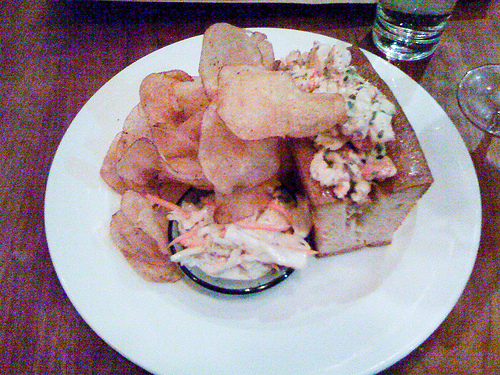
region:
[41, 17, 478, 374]
white plate on wood table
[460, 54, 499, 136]
base of wine glass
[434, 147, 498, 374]
shadow of plate on wood table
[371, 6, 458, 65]
clear glass cup on wood table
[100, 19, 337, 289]
crisps on white plate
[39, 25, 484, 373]
white plate with food on it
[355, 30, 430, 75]
shadow of glass on table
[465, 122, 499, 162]
shadow of wine glass on table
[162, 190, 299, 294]
small round dish on white plate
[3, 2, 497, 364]
wood table with plate and two glasses sitting on it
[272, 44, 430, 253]
lobster roll on a plate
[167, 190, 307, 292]
a small bowl of coleslaw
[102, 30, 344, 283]
kettle cooked potato chips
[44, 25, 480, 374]
a white plate with a sandwich and chips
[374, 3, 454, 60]
bottle of water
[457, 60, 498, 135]
bottom of a wine glass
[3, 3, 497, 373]
brown wooden table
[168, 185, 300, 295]
blue-rimmed tiny bowl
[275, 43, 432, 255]
lobster filling in a bun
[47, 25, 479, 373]
round white dinner plate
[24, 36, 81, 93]
The table is brown in color.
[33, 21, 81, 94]
The table is made from wood.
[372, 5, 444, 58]
The glass is clear.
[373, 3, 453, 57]
There is water in the glass.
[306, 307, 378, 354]
The plate is white.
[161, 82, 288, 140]
The chips are light in color.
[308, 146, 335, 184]
The shrimp is pink in color.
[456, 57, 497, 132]
The glass bottom in round.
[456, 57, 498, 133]
The glass bottom is clear.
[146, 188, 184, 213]
The carrot is orange.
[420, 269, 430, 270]
part of a plate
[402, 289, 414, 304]
edge of a plate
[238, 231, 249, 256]
part of the vegetable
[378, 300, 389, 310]
side of a plate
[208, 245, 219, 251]
part of a bowl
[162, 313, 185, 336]
edge of a bowl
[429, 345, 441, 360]
part of a table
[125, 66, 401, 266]
Food on the plate.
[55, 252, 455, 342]
The table is round is white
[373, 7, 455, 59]
A glass on water on the table.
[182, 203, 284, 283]
A cup of coleslaw on the plate.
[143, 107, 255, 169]
Chips on the plate.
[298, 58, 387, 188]
A chicken salad sanwich on plate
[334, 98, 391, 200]
Chicken salad between two breads.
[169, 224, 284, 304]
The small container is black.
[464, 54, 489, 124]
A bottom of a wine glass.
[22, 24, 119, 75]
The table is wood